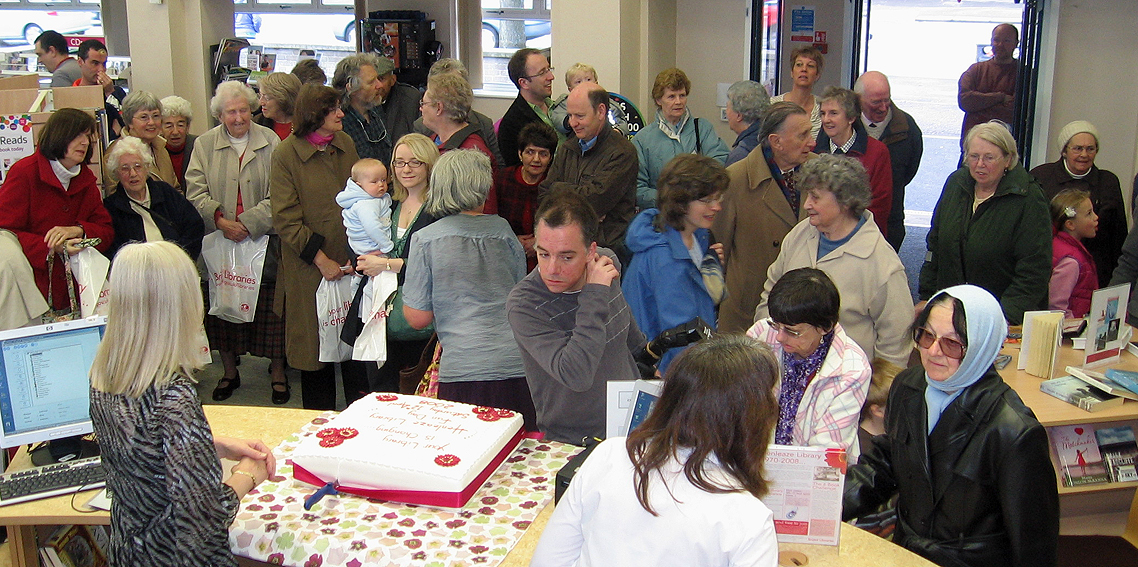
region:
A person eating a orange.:
[369, 383, 469, 530]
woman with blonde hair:
[81, 233, 246, 564]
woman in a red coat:
[8, 109, 115, 305]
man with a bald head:
[536, 77, 640, 246]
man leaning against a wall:
[944, 3, 1054, 160]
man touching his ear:
[505, 195, 649, 443]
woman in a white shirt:
[523, 333, 781, 563]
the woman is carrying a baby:
[333, 132, 435, 392]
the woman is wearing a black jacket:
[840, 281, 1059, 562]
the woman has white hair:
[89, 239, 277, 559]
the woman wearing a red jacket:
[0, 106, 113, 325]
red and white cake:
[302, 410, 510, 504]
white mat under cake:
[253, 390, 529, 562]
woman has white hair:
[65, 231, 276, 377]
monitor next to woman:
[0, 319, 149, 497]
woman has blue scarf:
[926, 260, 1030, 464]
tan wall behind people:
[1063, 0, 1115, 113]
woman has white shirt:
[542, 426, 792, 562]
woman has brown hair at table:
[634, 335, 754, 435]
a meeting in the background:
[70, 33, 1118, 520]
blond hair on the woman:
[64, 241, 312, 553]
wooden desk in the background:
[53, 210, 625, 553]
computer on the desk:
[5, 195, 180, 564]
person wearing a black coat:
[864, 260, 1124, 552]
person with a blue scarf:
[833, 234, 1019, 551]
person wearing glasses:
[771, 220, 1131, 522]